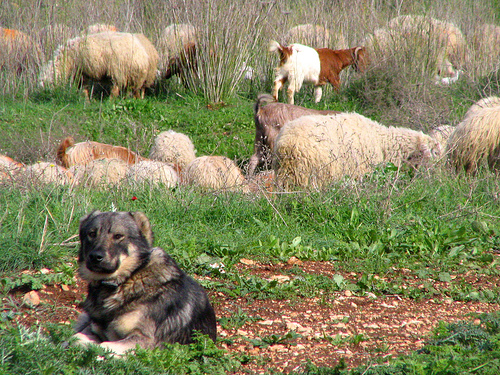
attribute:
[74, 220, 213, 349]
sheep dog — lying, laying, tan, black, resting, brown, sitting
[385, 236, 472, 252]
grass — tall, green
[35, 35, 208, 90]
sheep — standing, shaggy, tan, grazing, rowed, sitting, beige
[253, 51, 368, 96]
goat — brown, white, eating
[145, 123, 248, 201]
sheep — laying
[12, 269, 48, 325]
rock — tan, brown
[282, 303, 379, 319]
dirt — patched, brown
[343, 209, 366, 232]
leaf — green